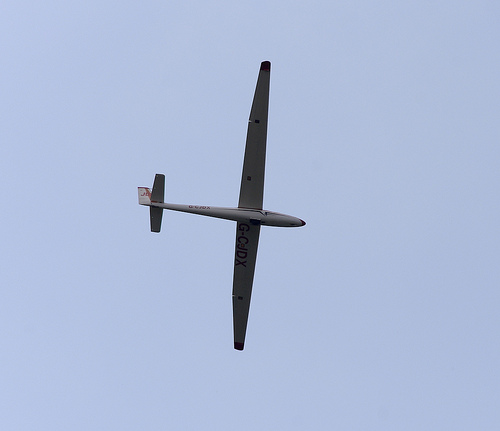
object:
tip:
[230, 340, 245, 351]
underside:
[143, 197, 305, 233]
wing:
[230, 224, 264, 350]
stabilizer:
[136, 184, 150, 207]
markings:
[138, 185, 151, 198]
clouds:
[434, 86, 458, 105]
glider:
[137, 60, 306, 351]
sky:
[440, 21, 497, 50]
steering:
[246, 116, 259, 125]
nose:
[290, 214, 307, 231]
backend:
[135, 171, 167, 231]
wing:
[236, 56, 275, 210]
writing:
[173, 203, 214, 215]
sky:
[120, 3, 159, 54]